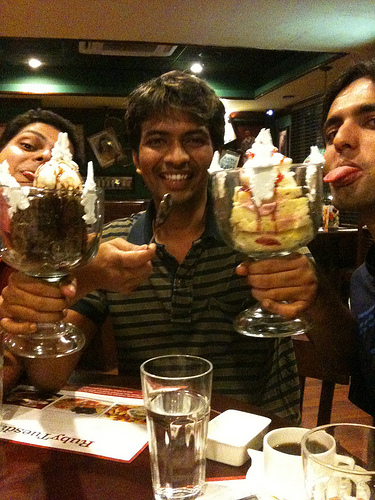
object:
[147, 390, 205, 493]
water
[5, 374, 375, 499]
table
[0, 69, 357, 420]
man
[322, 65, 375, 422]
person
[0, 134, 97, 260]
ice cream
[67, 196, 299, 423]
shirt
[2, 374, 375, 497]
mat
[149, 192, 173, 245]
spoon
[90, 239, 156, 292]
hand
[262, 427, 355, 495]
mug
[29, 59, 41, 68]
lights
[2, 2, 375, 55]
ceiling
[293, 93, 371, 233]
window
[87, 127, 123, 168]
picture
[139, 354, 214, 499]
glass